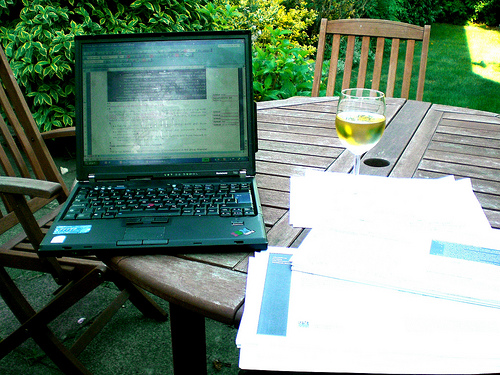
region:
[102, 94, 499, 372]
Wood table in the backyard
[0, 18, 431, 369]
Wood chairs in the backyard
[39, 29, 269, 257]
Laptop computer on the table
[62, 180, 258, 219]
Keyboard on the laptop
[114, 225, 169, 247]
Touchpad on the laptop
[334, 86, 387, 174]
Glass on the table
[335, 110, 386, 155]
Wine in the glass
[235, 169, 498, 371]
Papers on the table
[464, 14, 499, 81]
Sunlight on the grass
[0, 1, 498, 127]
Bushes in the backyard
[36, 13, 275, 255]
Black laptop sitting on a table.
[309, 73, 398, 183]
Glass of wine sitting on outdoor table.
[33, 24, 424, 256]
Black laptop with glass of wine next to it.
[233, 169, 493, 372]
Papers sitting on an outdoor table.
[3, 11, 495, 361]
Brown outdoor table setting with laptop.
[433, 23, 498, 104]
Green grass with a patch of sunlight.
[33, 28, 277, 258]
Working laptop with lit screen.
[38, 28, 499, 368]
Laptop with papers sitting on brown table.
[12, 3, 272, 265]
Bushes behind laptop on table.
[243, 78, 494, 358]
Wine glass with wine behind papers.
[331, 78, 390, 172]
Glass on a table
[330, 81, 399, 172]
Wine glass on a table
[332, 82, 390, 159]
Glass with wine in it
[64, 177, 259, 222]
Keyboard on a laptop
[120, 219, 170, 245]
Mouse pad on a laptop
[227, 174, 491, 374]
papers on a table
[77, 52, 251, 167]
Screen on a laptop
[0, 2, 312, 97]
Green leaves on bushes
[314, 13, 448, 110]
Brown chair by a table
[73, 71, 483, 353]
Table with a laptop on it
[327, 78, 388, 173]
glass of yellow beverage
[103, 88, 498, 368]
round wooden table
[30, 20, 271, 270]
open black laptop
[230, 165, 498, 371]
papers on top of round wooden table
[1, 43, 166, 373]
wooden folding chair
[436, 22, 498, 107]
grass on ground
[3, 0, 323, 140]
foliage on side of round wooden table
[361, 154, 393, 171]
round hole in center of round wooden table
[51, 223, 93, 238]
sticker on black laptop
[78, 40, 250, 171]
webpage on computer screen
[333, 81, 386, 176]
glass of white wine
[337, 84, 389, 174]
half full glass of wine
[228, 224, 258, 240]
IBM logo on laptop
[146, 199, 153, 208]
red mouse in middle of keyboard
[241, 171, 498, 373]
papers on wooden table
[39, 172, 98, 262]
side of laptop hanging off table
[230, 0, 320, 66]
yellow flowers between green bushes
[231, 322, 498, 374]
side of papers hanging off table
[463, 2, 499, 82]
sunlight reflecting on grass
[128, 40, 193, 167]
sunlight glare on laptop monitor